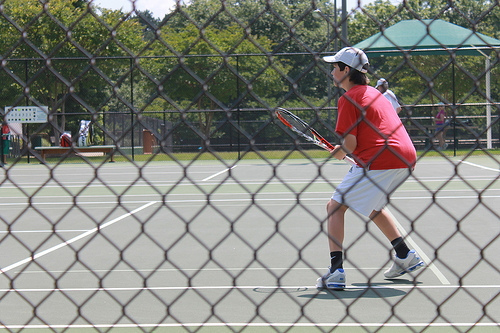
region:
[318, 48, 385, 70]
player wearing cap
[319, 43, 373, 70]
player wearing white cap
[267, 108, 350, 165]
player holding racquet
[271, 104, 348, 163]
player holding tennis racquet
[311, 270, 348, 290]
player wearing white and blue shoes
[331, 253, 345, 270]
player wearing black socks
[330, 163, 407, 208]
player wearing white shorts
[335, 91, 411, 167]
player wearing shirt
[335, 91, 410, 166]
player wearing red shirt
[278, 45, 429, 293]
player on tennis court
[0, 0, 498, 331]
Fence surrouding tennis court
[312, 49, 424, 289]
Person wearing a white tennis cap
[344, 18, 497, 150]
Green tent behind tennis courts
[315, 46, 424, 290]
Man wearing white sneakers with blue trim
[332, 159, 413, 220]
White knee high shorts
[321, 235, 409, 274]
Black calf length socks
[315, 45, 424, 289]
Man wearing red t-shirt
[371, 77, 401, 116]
Man wearing white cap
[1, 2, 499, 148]
Trees behind tennis courts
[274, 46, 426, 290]
Man waiting for tennis ball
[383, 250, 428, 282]
a woman's tennis shoe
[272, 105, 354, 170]
a red and white racket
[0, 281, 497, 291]
a long white line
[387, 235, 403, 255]
a black sock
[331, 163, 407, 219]
a woman's white shorts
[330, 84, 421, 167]
a woman's red shirt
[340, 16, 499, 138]
a tall green canopy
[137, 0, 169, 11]
a small white cloud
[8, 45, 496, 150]
a tall black chain link fence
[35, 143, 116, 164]
a long bench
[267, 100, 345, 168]
red and black tennis racquet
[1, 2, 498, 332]
black chain link fence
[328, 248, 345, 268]
black shin height socks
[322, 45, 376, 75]
white baseball cap on head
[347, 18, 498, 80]
green awning in distance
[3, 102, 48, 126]
white and black scoreboard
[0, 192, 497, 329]
tennis court with white lines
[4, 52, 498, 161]
tall black chain link fence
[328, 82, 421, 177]
person wearing red tee shirt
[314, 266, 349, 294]
white gray and blue tennis shoe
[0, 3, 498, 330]
A black chain link fence.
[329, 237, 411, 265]
A pair of black socks.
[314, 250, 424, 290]
A pair of white, grey, and light blue shoes.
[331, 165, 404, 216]
White sports shorts.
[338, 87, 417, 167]
A red short sleeved shirt.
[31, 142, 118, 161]
A bench.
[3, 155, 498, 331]
Two tennis courts.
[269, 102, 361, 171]
A tennis racket.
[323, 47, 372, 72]
A white ball cap.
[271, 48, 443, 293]
A boy holding a tennis racket.